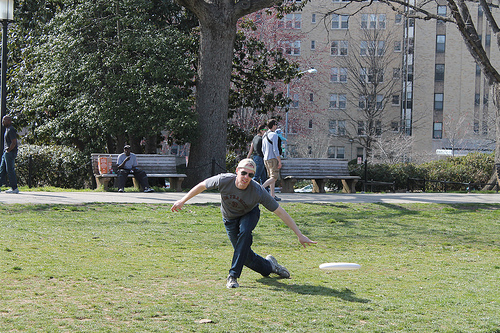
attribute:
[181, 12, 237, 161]
tree — big, between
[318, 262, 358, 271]
frisbee — white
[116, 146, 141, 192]
man — sitting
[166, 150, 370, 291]
man — playing